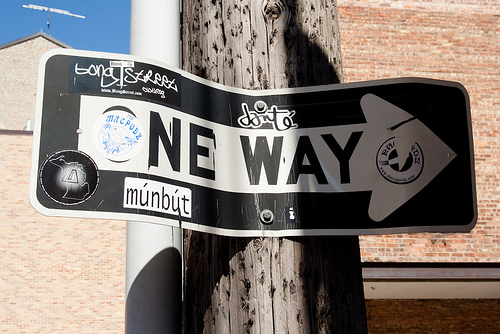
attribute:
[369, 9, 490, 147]
wall — brick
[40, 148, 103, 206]
sticker — black, circle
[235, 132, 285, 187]
letter "w" — w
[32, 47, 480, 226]
arrow — large, white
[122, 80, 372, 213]
sign — bent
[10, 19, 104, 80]
roof. — pointy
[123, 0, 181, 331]
pole — white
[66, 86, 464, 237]
white arrow — pointing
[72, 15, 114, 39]
sky — blue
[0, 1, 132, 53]
blue sky — clear, cloudless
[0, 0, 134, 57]
sky — blue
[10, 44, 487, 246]
sign — bent, light, dark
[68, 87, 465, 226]
arrow — white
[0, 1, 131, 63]
sky — blue, cloudless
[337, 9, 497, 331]
building — brick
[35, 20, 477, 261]
sign — black, white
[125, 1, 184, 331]
post — white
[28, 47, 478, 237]
one-way sign — bent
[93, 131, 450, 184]
arrow — large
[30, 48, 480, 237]
sign — black and white, broken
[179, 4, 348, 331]
post — brown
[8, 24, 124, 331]
building — brick